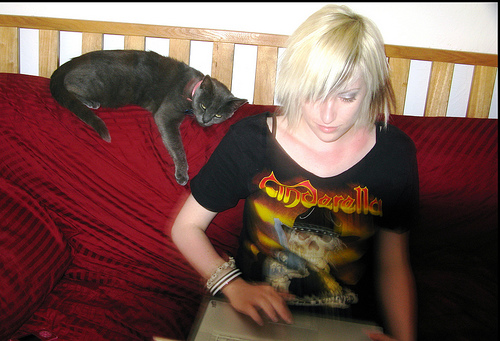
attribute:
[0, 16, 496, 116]
frame — wood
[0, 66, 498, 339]
couch — futon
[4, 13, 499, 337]
sofa — futon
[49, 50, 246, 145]
cat — black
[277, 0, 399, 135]
hair — dyed blonde, dark-rooted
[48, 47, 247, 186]
cat — black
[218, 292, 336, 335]
laptop — gray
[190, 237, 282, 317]
wrist — black, striped, girl's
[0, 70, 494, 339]
cushion — burgundy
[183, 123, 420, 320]
shirt — black, Cinderella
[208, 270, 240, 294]
bracelet — white